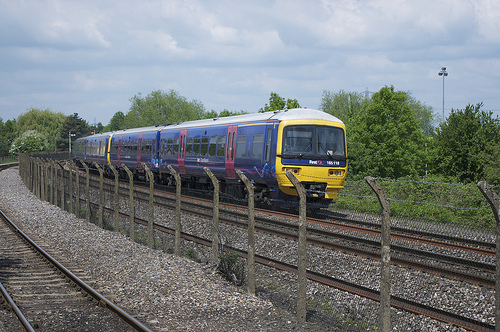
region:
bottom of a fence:
[303, 302, 316, 319]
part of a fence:
[304, 250, 316, 262]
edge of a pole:
[303, 262, 312, 288]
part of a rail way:
[70, 247, 89, 314]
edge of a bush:
[407, 119, 419, 142]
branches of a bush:
[401, 100, 406, 111]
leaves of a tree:
[401, 96, 409, 112]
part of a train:
[303, 113, 310, 117]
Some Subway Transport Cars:
[69, 100, 376, 217]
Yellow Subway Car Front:
[276, 101, 363, 215]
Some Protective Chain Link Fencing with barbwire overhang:
[121, 165, 260, 267]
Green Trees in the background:
[352, 82, 437, 182]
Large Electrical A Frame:
[356, 83, 381, 103]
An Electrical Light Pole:
[432, 60, 456, 130]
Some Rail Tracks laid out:
[0, 229, 97, 329]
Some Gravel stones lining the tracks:
[106, 243, 191, 302]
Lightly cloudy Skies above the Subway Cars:
[18, 11, 446, 66]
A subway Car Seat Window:
[233, 130, 247, 158]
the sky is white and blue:
[94, 29, 295, 165]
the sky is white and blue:
[48, 56, 293, 228]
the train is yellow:
[151, 91, 405, 240]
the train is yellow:
[198, 42, 380, 311]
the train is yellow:
[287, 118, 372, 267]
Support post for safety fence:
[279, 165, 316, 320]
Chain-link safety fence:
[405, 276, 442, 296]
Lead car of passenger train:
[158, 117, 353, 219]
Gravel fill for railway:
[135, 262, 170, 292]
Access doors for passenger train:
[218, 121, 245, 181]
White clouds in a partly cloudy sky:
[38, 14, 124, 62]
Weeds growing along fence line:
[205, 233, 257, 294]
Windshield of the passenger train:
[278, 115, 350, 166]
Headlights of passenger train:
[276, 164, 346, 181]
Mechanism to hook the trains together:
[307, 181, 325, 206]